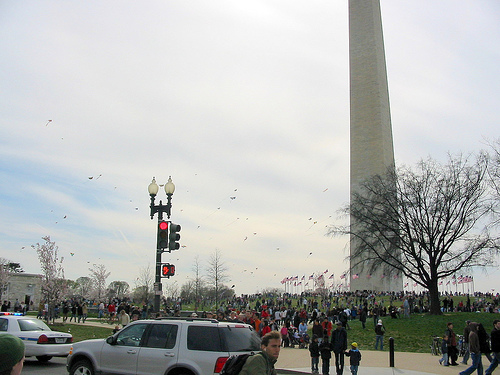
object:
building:
[0, 272, 46, 313]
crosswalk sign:
[162, 264, 175, 276]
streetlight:
[147, 175, 181, 277]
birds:
[217, 188, 249, 220]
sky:
[8, 164, 96, 233]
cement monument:
[346, 0, 405, 293]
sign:
[158, 219, 181, 276]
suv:
[66, 316, 265, 375]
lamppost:
[148, 175, 181, 317]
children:
[308, 333, 322, 372]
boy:
[343, 342, 362, 375]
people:
[70, 304, 77, 323]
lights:
[148, 175, 182, 280]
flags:
[280, 269, 475, 298]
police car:
[0, 311, 74, 362]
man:
[219, 330, 282, 375]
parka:
[238, 352, 276, 375]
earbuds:
[263, 347, 271, 361]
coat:
[344, 348, 361, 365]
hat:
[351, 342, 358, 348]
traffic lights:
[157, 220, 182, 250]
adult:
[330, 322, 347, 375]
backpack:
[217, 352, 271, 374]